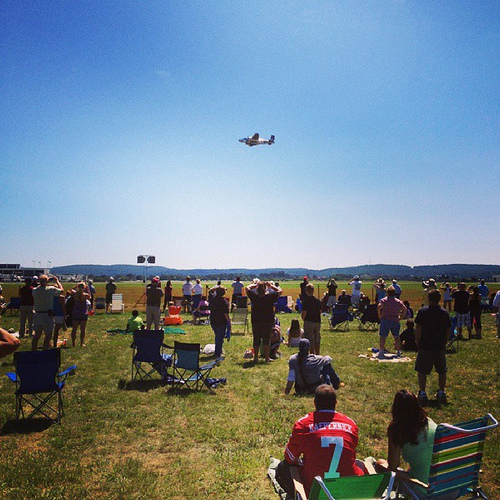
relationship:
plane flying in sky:
[238, 132, 276, 147] [3, 2, 496, 264]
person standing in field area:
[410, 282, 453, 407] [223, 318, 471, 430]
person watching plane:
[207, 285, 233, 360] [238, 132, 276, 144]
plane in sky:
[238, 132, 276, 144] [3, 2, 496, 264]